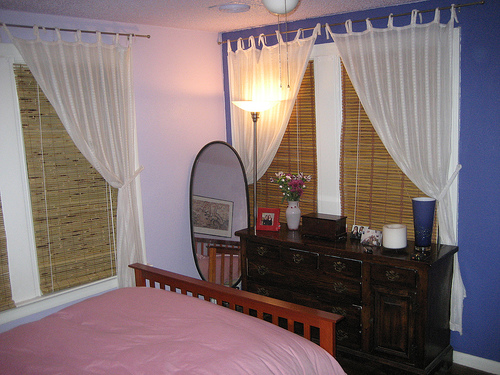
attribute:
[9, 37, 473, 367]
room — bed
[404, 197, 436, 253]
vase — purple, blue, ceramic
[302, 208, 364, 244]
box — jewelry, wooden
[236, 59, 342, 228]
blind — window, wooden, white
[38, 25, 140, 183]
curtain — white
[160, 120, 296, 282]
mirror — oval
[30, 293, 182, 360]
comforter — pink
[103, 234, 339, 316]
bed — wooden, pink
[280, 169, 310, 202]
flower — colorful, purple, pink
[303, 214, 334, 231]
chest — wooden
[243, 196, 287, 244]
frame — red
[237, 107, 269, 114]
housing — glass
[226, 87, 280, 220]
lamp — metal, standing, white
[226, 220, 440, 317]
dresser — wooden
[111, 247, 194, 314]
foot — wooden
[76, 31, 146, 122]
drape — white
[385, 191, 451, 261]
cup — large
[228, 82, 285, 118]
light — white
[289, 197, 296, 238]
vase — white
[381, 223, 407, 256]
candle — white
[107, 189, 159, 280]
leg — white